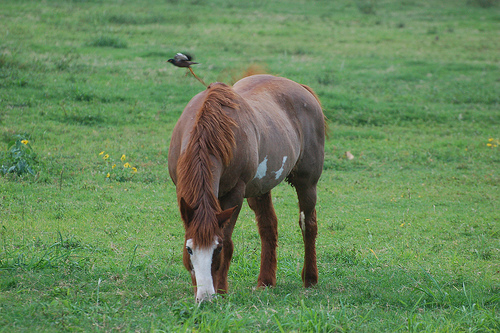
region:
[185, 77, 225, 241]
The mane of the horse standing up.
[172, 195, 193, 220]
The left ear of the horse.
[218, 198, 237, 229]
The right ear of the horse.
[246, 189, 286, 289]
The back left leg of the horse.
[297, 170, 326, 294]
The back right leg of the horse.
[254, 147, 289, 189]
The white horse on the horse's stomach area.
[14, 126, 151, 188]
The yellow flowers on the left side of the horse.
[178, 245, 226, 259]
The eyes of the horse.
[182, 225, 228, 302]
The white patch on the horse's face.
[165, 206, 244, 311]
The head of the horse.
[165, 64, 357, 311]
the horse is brown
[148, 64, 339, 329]
the horse has a white face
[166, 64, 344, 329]
the horse is eating grass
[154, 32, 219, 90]
the bird is flying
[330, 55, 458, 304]
the grass is green and lush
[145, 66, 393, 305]
the horse is standing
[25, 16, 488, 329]
the horse is in a meadow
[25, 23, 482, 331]
the horse and bird are alone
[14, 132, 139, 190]
a few yellow flowers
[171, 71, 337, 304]
the horse has white spots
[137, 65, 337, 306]
this is a horse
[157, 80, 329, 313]
the horse is brown in color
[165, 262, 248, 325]
the horse is feeding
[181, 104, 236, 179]
the fur is aligned in a line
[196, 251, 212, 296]
the face is white in color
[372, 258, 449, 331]
the grass are green in color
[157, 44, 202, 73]
this is a bird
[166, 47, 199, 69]
the bird is flying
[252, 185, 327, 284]
the legs are strong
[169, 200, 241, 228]
the ears are apart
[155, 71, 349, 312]
horse grazing in a field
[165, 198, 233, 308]
brown horse with a white face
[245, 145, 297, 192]
white spots on the side of a brown horse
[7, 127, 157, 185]
yellow flowers growing in a field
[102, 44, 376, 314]
brown horse in a field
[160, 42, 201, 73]
rock in the middle of a field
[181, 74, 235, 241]
shaggy brown mane of a horse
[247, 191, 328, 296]
back legs of a brown horse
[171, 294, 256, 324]
grass being eaten by a horse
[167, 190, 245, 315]
horse with alert ears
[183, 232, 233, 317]
Horse has white face.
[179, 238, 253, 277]
Horse has dark eyes.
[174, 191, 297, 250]
Horse has brown ears.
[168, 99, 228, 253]
Horse has brown mane.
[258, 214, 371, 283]
Horse has brown back legs.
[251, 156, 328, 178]
White spots on horse's side.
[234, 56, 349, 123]
Horse has brown tail.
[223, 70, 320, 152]
Horse has brown back.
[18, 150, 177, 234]
Yellow flowers sticking out of grass.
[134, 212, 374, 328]
Horse standing in grassy area.